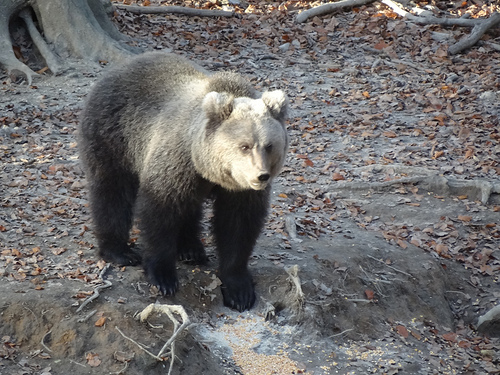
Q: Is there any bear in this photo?
A: Yes, there is a bear.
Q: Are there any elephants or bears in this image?
A: Yes, there is a bear.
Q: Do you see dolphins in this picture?
A: No, there are no dolphins.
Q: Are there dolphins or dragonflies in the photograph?
A: No, there are no dolphins or dragonflies.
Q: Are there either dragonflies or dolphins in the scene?
A: No, there are no dolphins or dragonflies.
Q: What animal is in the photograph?
A: The animal is a bear.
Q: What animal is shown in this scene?
A: The animal is a bear.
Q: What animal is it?
A: The animal is a bear.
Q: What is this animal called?
A: This is a bear.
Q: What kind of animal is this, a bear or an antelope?
A: This is a bear.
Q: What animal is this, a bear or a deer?
A: This is a bear.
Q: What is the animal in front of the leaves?
A: The animal is a bear.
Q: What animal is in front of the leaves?
A: The animal is a bear.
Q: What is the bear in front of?
A: The bear is in front of the leaves.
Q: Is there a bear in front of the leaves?
A: Yes, there is a bear in front of the leaves.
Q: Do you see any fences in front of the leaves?
A: No, there is a bear in front of the leaves.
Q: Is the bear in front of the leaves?
A: Yes, the bear is in front of the leaves.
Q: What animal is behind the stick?
A: The animal is a bear.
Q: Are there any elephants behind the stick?
A: No, there is a bear behind the stick.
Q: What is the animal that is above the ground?
A: The animal is a bear.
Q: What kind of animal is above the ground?
A: The animal is a bear.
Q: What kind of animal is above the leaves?
A: The animal is a bear.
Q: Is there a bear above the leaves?
A: Yes, there is a bear above the leaves.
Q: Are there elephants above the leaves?
A: No, there is a bear above the leaves.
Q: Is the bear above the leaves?
A: Yes, the bear is above the leaves.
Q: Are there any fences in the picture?
A: No, there are no fences.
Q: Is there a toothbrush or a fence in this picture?
A: No, there are no fences or toothbrushes.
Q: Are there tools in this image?
A: No, there are no tools.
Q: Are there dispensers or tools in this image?
A: No, there are no tools or dispensers.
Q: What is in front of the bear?
A: The stick is in front of the bear.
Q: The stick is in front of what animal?
A: The stick is in front of the bear.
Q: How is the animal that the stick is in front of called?
A: The animal is a bear.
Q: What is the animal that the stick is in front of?
A: The animal is a bear.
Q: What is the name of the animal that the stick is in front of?
A: The animal is a bear.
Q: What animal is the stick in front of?
A: The stick is in front of the bear.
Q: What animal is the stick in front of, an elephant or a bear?
A: The stick is in front of a bear.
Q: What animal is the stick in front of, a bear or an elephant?
A: The stick is in front of a bear.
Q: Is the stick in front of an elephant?
A: No, the stick is in front of the bear.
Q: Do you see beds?
A: No, there are no beds.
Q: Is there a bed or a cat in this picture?
A: No, there are no beds or cats.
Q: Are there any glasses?
A: No, there are no glasses.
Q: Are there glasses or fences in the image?
A: No, there are no glasses or fences.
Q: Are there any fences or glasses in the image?
A: No, there are no glasses or fences.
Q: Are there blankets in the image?
A: No, there are no blankets.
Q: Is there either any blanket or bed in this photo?
A: No, there are no blankets or beds.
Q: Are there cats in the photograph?
A: No, there are no cats.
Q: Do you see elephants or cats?
A: No, there are no cats or elephants.